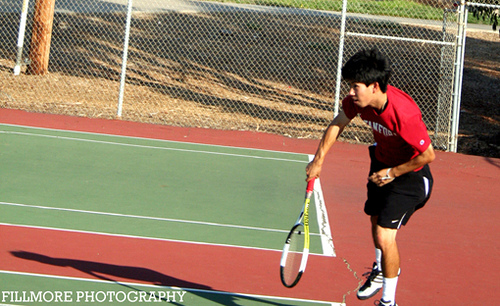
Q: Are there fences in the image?
A: Yes, there is a fence.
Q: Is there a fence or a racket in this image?
A: Yes, there is a fence.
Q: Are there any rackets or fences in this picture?
A: Yes, there is a fence.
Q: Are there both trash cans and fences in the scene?
A: No, there is a fence but no trash cans.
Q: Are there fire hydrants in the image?
A: No, there are no fire hydrants.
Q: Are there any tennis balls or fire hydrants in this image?
A: No, there are no fire hydrants or tennis balls.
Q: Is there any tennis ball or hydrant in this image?
A: No, there are no fire hydrants or tennis balls.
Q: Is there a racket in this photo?
A: Yes, there is a racket.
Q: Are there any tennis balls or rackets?
A: Yes, there is a racket.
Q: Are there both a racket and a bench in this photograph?
A: No, there is a racket but no benches.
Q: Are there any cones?
A: No, there are no cones.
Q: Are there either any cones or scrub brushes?
A: No, there are no cones or scrub brushes.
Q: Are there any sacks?
A: No, there are no sacks.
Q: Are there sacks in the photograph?
A: No, there are no sacks.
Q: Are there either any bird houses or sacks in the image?
A: No, there are no sacks or bird houses.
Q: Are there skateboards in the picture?
A: No, there are no skateboards.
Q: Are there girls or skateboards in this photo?
A: No, there are no skateboards or girls.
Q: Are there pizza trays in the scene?
A: No, there are no pizza trays.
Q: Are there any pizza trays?
A: No, there are no pizza trays.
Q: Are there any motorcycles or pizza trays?
A: No, there are no pizza trays or motorcycles.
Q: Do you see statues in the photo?
A: No, there are no statues.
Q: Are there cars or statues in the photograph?
A: No, there are no statues or cars.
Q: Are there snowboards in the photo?
A: No, there are no snowboards.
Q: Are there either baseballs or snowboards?
A: No, there are no snowboards or baseballs.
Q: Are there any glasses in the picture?
A: No, there are no glasses.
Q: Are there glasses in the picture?
A: No, there are no glasses.